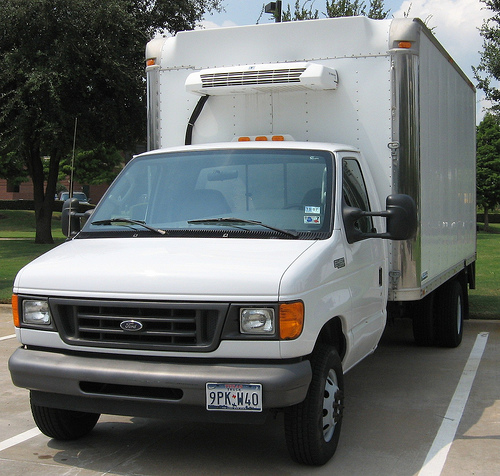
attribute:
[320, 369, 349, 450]
tire — black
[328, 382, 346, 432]
rim — white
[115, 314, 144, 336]
emblem — silver, blue, ford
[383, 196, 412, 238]
these mirror — black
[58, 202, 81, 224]
mirror — black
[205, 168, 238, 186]
mirror — black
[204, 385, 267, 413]
this license — texas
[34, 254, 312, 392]
this truck — ford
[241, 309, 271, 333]
this light — white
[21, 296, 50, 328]
light — white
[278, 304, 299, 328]
these light — orange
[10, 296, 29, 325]
these light — orange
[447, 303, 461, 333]
these tire — black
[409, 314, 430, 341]
these tire — black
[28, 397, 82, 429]
these tire — black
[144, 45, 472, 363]
truck — white, large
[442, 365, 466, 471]
these line — white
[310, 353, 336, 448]
this tire — black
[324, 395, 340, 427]
this rim — white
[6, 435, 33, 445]
this stripe — white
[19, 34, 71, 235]
this tree — large